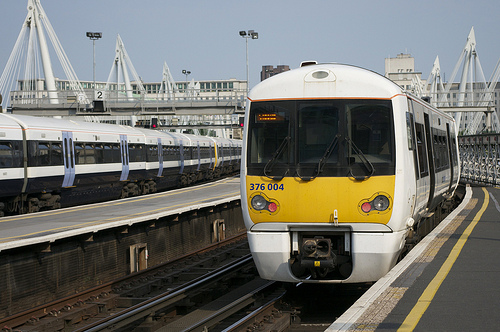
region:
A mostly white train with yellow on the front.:
[241, 62, 463, 284]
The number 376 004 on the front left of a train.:
[248, 180, 284, 192]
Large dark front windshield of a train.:
[247, 98, 397, 178]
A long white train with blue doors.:
[1, 110, 241, 192]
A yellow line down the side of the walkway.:
[396, 178, 491, 330]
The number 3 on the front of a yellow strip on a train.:
[247, 181, 255, 191]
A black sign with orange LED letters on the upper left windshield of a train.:
[253, 110, 285, 122]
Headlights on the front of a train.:
[250, 193, 390, 213]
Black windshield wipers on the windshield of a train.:
[263, 132, 375, 183]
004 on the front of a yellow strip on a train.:
[266, 183, 283, 191]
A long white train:
[0, 110, 241, 210]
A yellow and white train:
[235, 65, 460, 280]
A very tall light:
[235, 25, 255, 100]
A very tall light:
[180, 65, 190, 90]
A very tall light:
[85, 30, 100, 85]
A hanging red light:
[145, 110, 155, 125]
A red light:
[235, 111, 240, 121]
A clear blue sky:
[0, 0, 495, 90]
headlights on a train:
[250, 190, 390, 212]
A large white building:
[18, 76, 498, 137]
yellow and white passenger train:
[240, 61, 462, 282]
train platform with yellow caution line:
[320, 185, 498, 330]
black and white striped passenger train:
[0, 113, 242, 215]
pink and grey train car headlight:
[248, 191, 279, 216]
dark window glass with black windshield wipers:
[246, 98, 397, 180]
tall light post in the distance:
[86, 30, 101, 90]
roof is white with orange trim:
[247, 62, 406, 100]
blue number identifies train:
[248, 182, 283, 190]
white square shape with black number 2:
[94, 90, 103, 100]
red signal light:
[151, 118, 156, 127]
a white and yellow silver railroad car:
[247, 62, 457, 279]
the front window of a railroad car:
[242, 95, 397, 175]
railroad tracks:
[5, 235, 300, 326]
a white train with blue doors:
[0, 115, 240, 210]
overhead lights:
[235, 26, 265, 36]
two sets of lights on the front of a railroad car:
[250, 190, 386, 210]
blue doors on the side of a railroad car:
[60, 130, 75, 185]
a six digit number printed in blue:
[247, 180, 285, 190]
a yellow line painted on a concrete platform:
[400, 190, 488, 329]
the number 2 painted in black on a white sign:
[94, 86, 106, 101]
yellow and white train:
[237, 61, 467, 291]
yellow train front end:
[243, 163, 400, 232]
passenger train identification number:
[245, 180, 288, 192]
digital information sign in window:
[252, 110, 287, 124]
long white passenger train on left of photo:
[2, 108, 247, 213]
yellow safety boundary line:
[388, 184, 490, 330]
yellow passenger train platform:
[314, 181, 499, 328]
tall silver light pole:
[235, 27, 260, 103]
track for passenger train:
[0, 220, 364, 330]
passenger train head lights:
[250, 193, 392, 213]